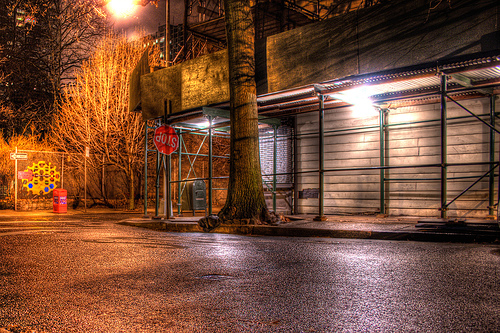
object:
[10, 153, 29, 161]
sign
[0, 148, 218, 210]
fence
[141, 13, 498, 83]
scaffolding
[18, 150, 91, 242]
gate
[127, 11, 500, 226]
building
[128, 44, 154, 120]
wood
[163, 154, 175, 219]
pole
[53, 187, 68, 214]
trash can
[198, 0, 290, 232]
tree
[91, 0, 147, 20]
nighttime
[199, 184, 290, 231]
trunk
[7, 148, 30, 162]
sign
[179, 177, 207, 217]
can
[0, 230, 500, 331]
street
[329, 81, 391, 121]
light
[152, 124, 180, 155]
sign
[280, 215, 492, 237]
sidewalk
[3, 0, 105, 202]
trees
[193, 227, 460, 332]
reflection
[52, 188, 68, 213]
box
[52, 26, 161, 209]
tree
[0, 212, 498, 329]
ground